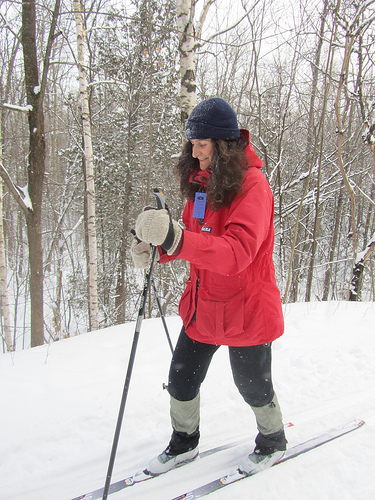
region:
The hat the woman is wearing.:
[179, 101, 239, 140]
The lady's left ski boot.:
[142, 440, 203, 475]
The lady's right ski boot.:
[233, 450, 294, 473]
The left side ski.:
[62, 421, 296, 499]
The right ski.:
[160, 390, 372, 498]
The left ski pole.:
[147, 272, 174, 355]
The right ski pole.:
[104, 242, 165, 499]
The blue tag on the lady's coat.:
[190, 189, 206, 220]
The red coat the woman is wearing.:
[171, 130, 289, 353]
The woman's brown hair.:
[175, 141, 246, 212]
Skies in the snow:
[114, 436, 300, 496]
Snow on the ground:
[51, 342, 79, 392]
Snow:
[47, 391, 111, 444]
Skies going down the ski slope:
[77, 344, 352, 496]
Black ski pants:
[111, 283, 307, 426]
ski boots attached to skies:
[115, 440, 226, 474]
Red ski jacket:
[124, 136, 289, 329]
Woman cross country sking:
[148, 69, 347, 471]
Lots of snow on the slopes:
[46, 369, 110, 436]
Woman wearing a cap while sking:
[172, 87, 261, 164]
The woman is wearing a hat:
[181, 96, 260, 142]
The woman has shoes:
[143, 425, 211, 471]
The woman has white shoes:
[132, 439, 207, 476]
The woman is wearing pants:
[154, 316, 219, 412]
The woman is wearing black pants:
[170, 323, 215, 416]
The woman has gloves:
[106, 214, 189, 254]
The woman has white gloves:
[115, 209, 190, 245]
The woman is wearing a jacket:
[144, 167, 298, 358]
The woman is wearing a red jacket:
[149, 196, 285, 350]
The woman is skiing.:
[136, 183, 357, 491]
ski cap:
[184, 96, 242, 142]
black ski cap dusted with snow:
[183, 96, 243, 144]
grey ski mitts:
[128, 207, 184, 268]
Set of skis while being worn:
[63, 415, 368, 497]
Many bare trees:
[0, 0, 373, 355]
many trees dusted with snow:
[2, 0, 374, 354]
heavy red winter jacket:
[151, 127, 283, 346]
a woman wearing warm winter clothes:
[70, 96, 367, 498]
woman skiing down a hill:
[73, 96, 366, 498]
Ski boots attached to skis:
[141, 424, 288, 477]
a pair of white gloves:
[126, 206, 182, 264]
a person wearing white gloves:
[124, 88, 291, 480]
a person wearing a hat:
[128, 94, 290, 478]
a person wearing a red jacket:
[122, 94, 292, 483]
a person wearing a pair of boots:
[114, 90, 290, 480]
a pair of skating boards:
[69, 413, 364, 498]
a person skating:
[76, 88, 366, 495]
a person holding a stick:
[104, 90, 314, 495]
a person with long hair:
[109, 95, 297, 489]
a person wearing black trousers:
[130, 101, 291, 479]